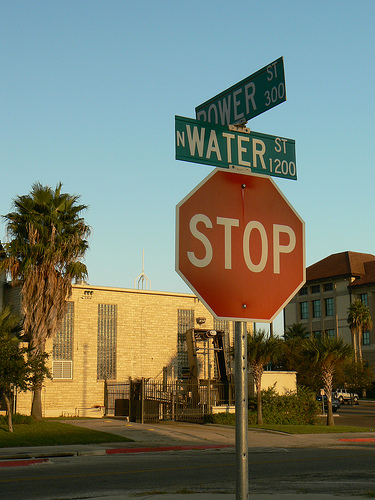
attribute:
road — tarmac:
[1, 439, 375, 495]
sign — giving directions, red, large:
[174, 166, 308, 322]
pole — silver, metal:
[233, 322, 252, 499]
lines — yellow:
[2, 452, 373, 484]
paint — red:
[2, 435, 374, 469]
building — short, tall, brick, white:
[7, 281, 298, 417]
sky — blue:
[1, 2, 375, 342]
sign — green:
[175, 115, 299, 182]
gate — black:
[106, 376, 253, 427]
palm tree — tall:
[1, 180, 94, 421]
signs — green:
[175, 56, 299, 179]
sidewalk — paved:
[1, 430, 374, 467]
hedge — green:
[204, 381, 320, 425]